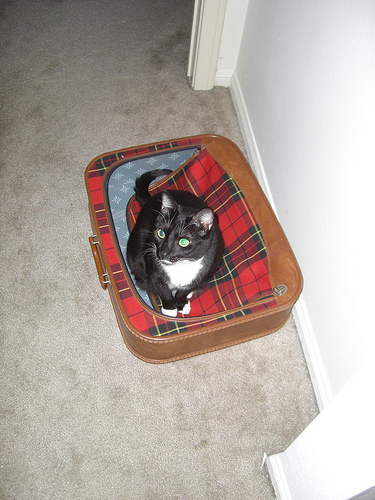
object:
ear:
[190, 207, 215, 239]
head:
[154, 194, 218, 263]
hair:
[175, 195, 204, 227]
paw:
[159, 304, 178, 320]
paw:
[177, 297, 191, 315]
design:
[109, 169, 125, 182]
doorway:
[184, 0, 228, 94]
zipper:
[199, 127, 224, 147]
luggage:
[83, 126, 305, 365]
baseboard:
[225, 75, 320, 410]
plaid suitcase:
[83, 120, 306, 368]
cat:
[124, 160, 228, 317]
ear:
[159, 192, 178, 214]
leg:
[152, 278, 179, 320]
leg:
[175, 285, 193, 316]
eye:
[174, 237, 193, 247]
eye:
[154, 227, 168, 238]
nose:
[157, 244, 169, 258]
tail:
[131, 164, 176, 208]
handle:
[86, 231, 111, 292]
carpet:
[0, 1, 258, 497]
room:
[0, 2, 374, 498]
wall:
[244, 4, 363, 385]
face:
[156, 203, 209, 263]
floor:
[0, 5, 345, 497]